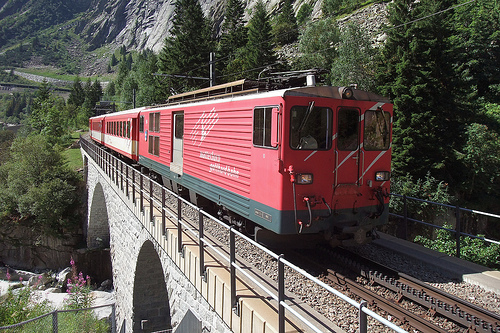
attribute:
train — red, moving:
[84, 81, 395, 251]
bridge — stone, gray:
[70, 136, 499, 332]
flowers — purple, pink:
[65, 257, 89, 295]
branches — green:
[71, 296, 87, 309]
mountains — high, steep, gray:
[103, 3, 240, 41]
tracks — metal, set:
[303, 243, 491, 332]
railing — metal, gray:
[98, 147, 403, 332]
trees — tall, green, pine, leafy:
[376, 0, 499, 207]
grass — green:
[57, 125, 84, 171]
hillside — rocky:
[81, 4, 122, 37]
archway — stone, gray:
[83, 181, 124, 317]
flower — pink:
[31, 274, 43, 295]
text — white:
[197, 150, 240, 179]